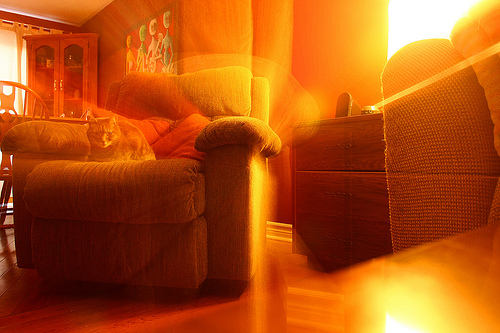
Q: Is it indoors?
A: Yes, it is indoors.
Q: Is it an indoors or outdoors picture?
A: It is indoors.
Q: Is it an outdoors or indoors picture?
A: It is indoors.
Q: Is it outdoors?
A: No, it is indoors.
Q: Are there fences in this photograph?
A: No, there are no fences.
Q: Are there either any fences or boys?
A: No, there are no fences or boys.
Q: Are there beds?
A: No, there are no beds.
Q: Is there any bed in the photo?
A: No, there are no beds.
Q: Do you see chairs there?
A: Yes, there is a chair.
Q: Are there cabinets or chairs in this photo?
A: Yes, there is a chair.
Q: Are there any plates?
A: No, there are no plates.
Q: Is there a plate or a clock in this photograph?
A: No, there are no plates or clocks.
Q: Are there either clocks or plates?
A: No, there are no plates or clocks.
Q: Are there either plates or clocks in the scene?
A: No, there are no plates or clocks.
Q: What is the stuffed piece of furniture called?
A: The piece of furniture is a chair.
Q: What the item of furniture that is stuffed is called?
A: The piece of furniture is a chair.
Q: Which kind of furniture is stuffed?
A: The furniture is a chair.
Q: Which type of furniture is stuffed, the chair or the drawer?
A: The chair is stuffed.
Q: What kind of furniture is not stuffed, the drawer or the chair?
A: The drawer is not stuffed.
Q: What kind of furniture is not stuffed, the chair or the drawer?
A: The drawer is not stuffed.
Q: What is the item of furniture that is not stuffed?
A: The piece of furniture is a drawer.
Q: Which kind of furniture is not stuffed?
A: The furniture is a drawer.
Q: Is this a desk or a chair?
A: This is a chair.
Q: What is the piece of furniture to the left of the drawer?
A: The piece of furniture is a chair.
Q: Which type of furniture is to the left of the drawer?
A: The piece of furniture is a chair.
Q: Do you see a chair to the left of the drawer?
A: Yes, there is a chair to the left of the drawer.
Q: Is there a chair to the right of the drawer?
A: No, the chair is to the left of the drawer.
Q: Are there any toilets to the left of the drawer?
A: No, there is a chair to the left of the drawer.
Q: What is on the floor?
A: The chair is on the floor.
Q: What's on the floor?
A: The chair is on the floor.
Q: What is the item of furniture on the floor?
A: The piece of furniture is a chair.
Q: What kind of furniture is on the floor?
A: The piece of furniture is a chair.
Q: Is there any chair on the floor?
A: Yes, there is a chair on the floor.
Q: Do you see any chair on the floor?
A: Yes, there is a chair on the floor.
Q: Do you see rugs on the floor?
A: No, there is a chair on the floor.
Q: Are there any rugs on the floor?
A: No, there is a chair on the floor.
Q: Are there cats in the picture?
A: Yes, there is a cat.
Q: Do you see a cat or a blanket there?
A: Yes, there is a cat.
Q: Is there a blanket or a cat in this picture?
A: Yes, there is a cat.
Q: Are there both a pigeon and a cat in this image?
A: No, there is a cat but no pigeons.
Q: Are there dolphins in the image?
A: No, there are no dolphins.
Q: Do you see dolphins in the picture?
A: No, there are no dolphins.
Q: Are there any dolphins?
A: No, there are no dolphins.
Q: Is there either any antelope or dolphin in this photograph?
A: No, there are no dolphins or antelopes.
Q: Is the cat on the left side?
A: Yes, the cat is on the left of the image.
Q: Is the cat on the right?
A: No, the cat is on the left of the image.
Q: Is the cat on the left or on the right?
A: The cat is on the left of the image.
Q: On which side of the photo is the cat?
A: The cat is on the left of the image.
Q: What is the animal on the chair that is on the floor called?
A: The animal is a cat.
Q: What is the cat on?
A: The cat is on the chair.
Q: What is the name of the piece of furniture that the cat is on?
A: The piece of furniture is a chair.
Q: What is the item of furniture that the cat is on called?
A: The piece of furniture is a chair.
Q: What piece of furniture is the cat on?
A: The cat is on the chair.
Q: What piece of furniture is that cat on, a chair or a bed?
A: The cat is on a chair.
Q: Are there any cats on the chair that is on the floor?
A: Yes, there is a cat on the chair.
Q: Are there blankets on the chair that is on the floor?
A: No, there is a cat on the chair.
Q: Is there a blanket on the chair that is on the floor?
A: No, there is a cat on the chair.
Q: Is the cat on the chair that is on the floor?
A: Yes, the cat is on the chair.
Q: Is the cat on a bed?
A: No, the cat is on the chair.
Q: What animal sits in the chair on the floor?
A: The cat sits in the chair.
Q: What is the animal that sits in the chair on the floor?
A: The animal is a cat.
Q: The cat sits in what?
A: The cat sits in the chair.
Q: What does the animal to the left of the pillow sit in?
A: The cat sits in the chair.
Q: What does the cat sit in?
A: The cat sits in the chair.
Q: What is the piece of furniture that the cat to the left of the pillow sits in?
A: The piece of furniture is a chair.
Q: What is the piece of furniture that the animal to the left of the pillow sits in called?
A: The piece of furniture is a chair.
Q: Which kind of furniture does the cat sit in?
A: The cat sits in the chair.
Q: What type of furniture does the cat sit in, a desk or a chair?
A: The cat sits in a chair.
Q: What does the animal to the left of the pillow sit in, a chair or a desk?
A: The cat sits in a chair.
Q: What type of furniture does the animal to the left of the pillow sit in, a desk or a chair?
A: The cat sits in a chair.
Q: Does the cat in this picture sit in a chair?
A: Yes, the cat sits in a chair.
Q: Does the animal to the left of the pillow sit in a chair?
A: Yes, the cat sits in a chair.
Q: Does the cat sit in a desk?
A: No, the cat sits in a chair.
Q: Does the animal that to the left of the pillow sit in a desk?
A: No, the cat sits in a chair.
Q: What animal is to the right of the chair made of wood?
A: The animal is a cat.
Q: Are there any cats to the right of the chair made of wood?
A: Yes, there is a cat to the right of the chair.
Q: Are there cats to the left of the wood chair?
A: No, the cat is to the right of the chair.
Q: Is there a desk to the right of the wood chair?
A: No, there is a cat to the right of the chair.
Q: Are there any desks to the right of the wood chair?
A: No, there is a cat to the right of the chair.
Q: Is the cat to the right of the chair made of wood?
A: Yes, the cat is to the right of the chair.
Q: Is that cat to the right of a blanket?
A: No, the cat is to the right of the chair.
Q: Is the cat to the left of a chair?
A: No, the cat is to the right of a chair.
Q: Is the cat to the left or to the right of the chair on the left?
A: The cat is to the right of the chair.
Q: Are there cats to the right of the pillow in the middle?
A: No, the cat is to the left of the pillow.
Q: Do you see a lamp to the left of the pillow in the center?
A: No, there is a cat to the left of the pillow.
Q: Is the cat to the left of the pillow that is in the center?
A: Yes, the cat is to the left of the pillow.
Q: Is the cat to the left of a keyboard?
A: No, the cat is to the left of the pillow.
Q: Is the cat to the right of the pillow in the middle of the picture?
A: No, the cat is to the left of the pillow.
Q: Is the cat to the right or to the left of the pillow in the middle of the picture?
A: The cat is to the left of the pillow.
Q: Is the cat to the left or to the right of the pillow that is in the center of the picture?
A: The cat is to the left of the pillow.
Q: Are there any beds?
A: No, there are no beds.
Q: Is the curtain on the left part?
A: Yes, the curtain is on the left of the image.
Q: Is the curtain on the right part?
A: No, the curtain is on the left of the image.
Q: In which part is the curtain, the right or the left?
A: The curtain is on the left of the image.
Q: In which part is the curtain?
A: The curtain is on the left of the image.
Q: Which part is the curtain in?
A: The curtain is on the left of the image.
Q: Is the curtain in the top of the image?
A: Yes, the curtain is in the top of the image.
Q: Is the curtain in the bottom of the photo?
A: No, the curtain is in the top of the image.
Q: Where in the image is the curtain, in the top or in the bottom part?
A: The curtain is in the top of the image.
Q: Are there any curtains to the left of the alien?
A: Yes, there is a curtain to the left of the alien.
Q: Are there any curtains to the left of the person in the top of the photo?
A: Yes, there is a curtain to the left of the alien.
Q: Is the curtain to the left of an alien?
A: Yes, the curtain is to the left of an alien.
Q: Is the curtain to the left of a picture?
A: No, the curtain is to the left of an alien.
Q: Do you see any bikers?
A: No, there are no bikers.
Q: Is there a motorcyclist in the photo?
A: No, there are no bikers.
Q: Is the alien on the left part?
A: Yes, the alien is on the left of the image.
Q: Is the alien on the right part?
A: No, the alien is on the left of the image.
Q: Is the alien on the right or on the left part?
A: The alien is on the left of the image.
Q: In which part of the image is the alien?
A: The alien is on the left of the image.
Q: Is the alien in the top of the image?
A: Yes, the alien is in the top of the image.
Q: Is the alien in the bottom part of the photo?
A: No, the alien is in the top of the image.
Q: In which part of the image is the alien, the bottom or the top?
A: The alien is in the top of the image.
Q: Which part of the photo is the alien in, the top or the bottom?
A: The alien is in the top of the image.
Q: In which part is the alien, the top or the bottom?
A: The alien is in the top of the image.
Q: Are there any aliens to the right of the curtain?
A: Yes, there is an alien to the right of the curtain.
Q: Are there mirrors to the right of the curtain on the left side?
A: No, there is an alien to the right of the curtain.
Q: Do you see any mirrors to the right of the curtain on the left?
A: No, there is an alien to the right of the curtain.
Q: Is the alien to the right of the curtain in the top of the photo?
A: Yes, the alien is to the right of the curtain.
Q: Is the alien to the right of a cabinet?
A: Yes, the alien is to the right of a cabinet.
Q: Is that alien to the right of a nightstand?
A: No, the alien is to the right of a cabinet.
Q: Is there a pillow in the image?
A: Yes, there is a pillow.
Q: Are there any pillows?
A: Yes, there is a pillow.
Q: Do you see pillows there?
A: Yes, there is a pillow.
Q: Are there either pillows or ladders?
A: Yes, there is a pillow.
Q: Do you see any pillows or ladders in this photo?
A: Yes, there is a pillow.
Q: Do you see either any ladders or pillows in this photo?
A: Yes, there is a pillow.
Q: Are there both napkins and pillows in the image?
A: No, there is a pillow but no napkins.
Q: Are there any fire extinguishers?
A: No, there are no fire extinguishers.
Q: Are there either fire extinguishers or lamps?
A: No, there are no fire extinguishers or lamps.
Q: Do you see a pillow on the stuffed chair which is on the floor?
A: Yes, there is a pillow on the chair.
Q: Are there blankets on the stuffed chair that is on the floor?
A: No, there is a pillow on the chair.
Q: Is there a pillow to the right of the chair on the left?
A: Yes, there is a pillow to the right of the chair.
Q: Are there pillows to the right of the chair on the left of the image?
A: Yes, there is a pillow to the right of the chair.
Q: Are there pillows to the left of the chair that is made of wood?
A: No, the pillow is to the right of the chair.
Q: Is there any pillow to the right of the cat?
A: Yes, there is a pillow to the right of the cat.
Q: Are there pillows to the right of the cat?
A: Yes, there is a pillow to the right of the cat.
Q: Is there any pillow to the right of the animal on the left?
A: Yes, there is a pillow to the right of the cat.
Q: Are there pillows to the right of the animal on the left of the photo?
A: Yes, there is a pillow to the right of the cat.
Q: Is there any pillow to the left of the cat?
A: No, the pillow is to the right of the cat.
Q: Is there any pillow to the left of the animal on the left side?
A: No, the pillow is to the right of the cat.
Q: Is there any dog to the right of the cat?
A: No, there is a pillow to the right of the cat.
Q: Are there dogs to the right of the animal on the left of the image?
A: No, there is a pillow to the right of the cat.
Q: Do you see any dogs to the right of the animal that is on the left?
A: No, there is a pillow to the right of the cat.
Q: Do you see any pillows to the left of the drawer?
A: Yes, there is a pillow to the left of the drawer.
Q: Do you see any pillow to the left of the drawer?
A: Yes, there is a pillow to the left of the drawer.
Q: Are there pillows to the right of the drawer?
A: No, the pillow is to the left of the drawer.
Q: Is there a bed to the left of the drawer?
A: No, there is a pillow to the left of the drawer.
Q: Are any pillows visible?
A: Yes, there is a pillow.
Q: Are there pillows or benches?
A: Yes, there is a pillow.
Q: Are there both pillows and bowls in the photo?
A: No, there is a pillow but no bowls.